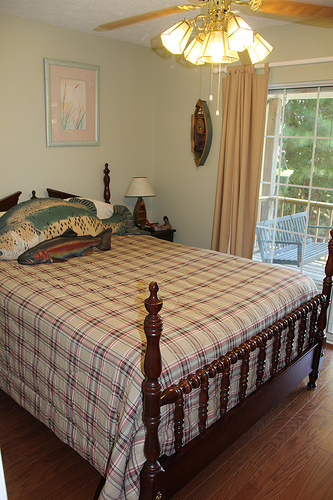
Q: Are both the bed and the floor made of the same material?
A: Yes, both the bed and the floor are made of wood.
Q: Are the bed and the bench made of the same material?
A: Yes, both the bed and the bench are made of wood.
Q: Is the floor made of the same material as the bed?
A: Yes, both the floor and the bed are made of wood.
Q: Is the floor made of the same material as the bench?
A: Yes, both the floor and the bench are made of wood.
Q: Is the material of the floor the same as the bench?
A: Yes, both the floor and the bench are made of wood.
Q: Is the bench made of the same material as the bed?
A: Yes, both the bench and the bed are made of wood.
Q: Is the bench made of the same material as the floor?
A: Yes, both the bench and the floor are made of wood.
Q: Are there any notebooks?
A: No, there are no notebooks.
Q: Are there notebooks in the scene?
A: No, there are no notebooks.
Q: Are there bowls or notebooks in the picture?
A: No, there are no notebooks or bowls.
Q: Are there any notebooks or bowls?
A: No, there are no notebooks or bowls.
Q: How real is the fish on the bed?
A: The fish is fake.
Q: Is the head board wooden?
A: Yes, the head board is wooden.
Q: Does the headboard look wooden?
A: Yes, the headboard is wooden.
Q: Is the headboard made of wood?
A: Yes, the headboard is made of wood.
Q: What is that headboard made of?
A: The headboard is made of wood.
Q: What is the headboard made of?
A: The headboard is made of wood.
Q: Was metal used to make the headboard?
A: No, the headboard is made of wood.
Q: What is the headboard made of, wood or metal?
A: The headboard is made of wood.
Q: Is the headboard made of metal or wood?
A: The headboard is made of wood.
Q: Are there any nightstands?
A: Yes, there is a nightstand.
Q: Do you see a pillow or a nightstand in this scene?
A: Yes, there is a nightstand.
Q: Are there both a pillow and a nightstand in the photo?
A: Yes, there are both a nightstand and a pillow.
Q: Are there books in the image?
A: No, there are no books.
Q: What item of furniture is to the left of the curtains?
A: The piece of furniture is a nightstand.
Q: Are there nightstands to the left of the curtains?
A: Yes, there is a nightstand to the left of the curtains.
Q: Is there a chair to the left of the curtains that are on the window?
A: No, there is a nightstand to the left of the curtains.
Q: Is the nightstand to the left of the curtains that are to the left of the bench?
A: Yes, the nightstand is to the left of the curtains.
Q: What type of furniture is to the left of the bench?
A: The piece of furniture is a nightstand.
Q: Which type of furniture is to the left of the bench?
A: The piece of furniture is a nightstand.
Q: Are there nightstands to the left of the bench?
A: Yes, there is a nightstand to the left of the bench.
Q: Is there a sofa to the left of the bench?
A: No, there is a nightstand to the left of the bench.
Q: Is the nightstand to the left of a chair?
A: No, the nightstand is to the left of the bench.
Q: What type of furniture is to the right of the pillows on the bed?
A: The piece of furniture is a nightstand.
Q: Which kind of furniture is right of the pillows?
A: The piece of furniture is a nightstand.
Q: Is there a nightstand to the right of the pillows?
A: Yes, there is a nightstand to the right of the pillows.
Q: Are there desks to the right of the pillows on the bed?
A: No, there is a nightstand to the right of the pillows.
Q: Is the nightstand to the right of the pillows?
A: Yes, the nightstand is to the right of the pillows.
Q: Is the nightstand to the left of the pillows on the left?
A: No, the nightstand is to the right of the pillows.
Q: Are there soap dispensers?
A: No, there are no soap dispensers.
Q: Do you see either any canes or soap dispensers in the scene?
A: No, there are no soap dispensers or canes.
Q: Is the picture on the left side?
A: Yes, the picture is on the left of the image.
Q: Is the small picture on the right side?
A: No, the picture is on the left of the image.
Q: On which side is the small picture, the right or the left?
A: The picture is on the left of the image.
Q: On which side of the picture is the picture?
A: The picture is on the left of the image.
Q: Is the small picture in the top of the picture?
A: Yes, the picture is in the top of the image.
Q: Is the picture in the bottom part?
A: No, the picture is in the top of the image.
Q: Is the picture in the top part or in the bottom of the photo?
A: The picture is in the top of the image.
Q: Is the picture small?
A: Yes, the picture is small.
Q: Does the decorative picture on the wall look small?
A: Yes, the picture is small.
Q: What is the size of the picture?
A: The picture is small.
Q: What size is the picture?
A: The picture is small.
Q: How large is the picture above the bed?
A: The picture is small.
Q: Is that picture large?
A: No, the picture is small.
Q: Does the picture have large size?
A: No, the picture is small.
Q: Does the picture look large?
A: No, the picture is small.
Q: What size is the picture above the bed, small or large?
A: The picture is small.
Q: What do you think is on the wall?
A: The picture is on the wall.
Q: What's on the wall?
A: The picture is on the wall.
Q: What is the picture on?
A: The picture is on the wall.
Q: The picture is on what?
A: The picture is on the wall.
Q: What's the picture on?
A: The picture is on the wall.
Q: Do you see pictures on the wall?
A: Yes, there is a picture on the wall.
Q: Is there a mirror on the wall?
A: No, there is a picture on the wall.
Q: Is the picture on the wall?
A: Yes, the picture is on the wall.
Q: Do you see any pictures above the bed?
A: Yes, there is a picture above the bed.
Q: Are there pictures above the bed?
A: Yes, there is a picture above the bed.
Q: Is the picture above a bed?
A: Yes, the picture is above a bed.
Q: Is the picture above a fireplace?
A: No, the picture is above a bed.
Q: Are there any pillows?
A: Yes, there are pillows.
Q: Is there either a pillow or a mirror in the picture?
A: Yes, there are pillows.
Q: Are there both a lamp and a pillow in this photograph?
A: Yes, there are both a pillow and a lamp.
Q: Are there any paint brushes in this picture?
A: No, there are no paint brushes.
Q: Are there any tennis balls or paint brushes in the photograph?
A: No, there are no paint brushes or tennis balls.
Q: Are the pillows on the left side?
A: Yes, the pillows are on the left of the image.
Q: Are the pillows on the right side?
A: No, the pillows are on the left of the image.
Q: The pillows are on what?
A: The pillows are on the bed.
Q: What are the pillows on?
A: The pillows are on the bed.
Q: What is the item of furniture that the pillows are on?
A: The piece of furniture is a bed.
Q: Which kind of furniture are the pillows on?
A: The pillows are on the bed.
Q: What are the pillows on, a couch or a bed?
A: The pillows are on a bed.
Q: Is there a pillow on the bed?
A: Yes, there are pillows on the bed.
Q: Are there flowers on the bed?
A: No, there are pillows on the bed.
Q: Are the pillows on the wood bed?
A: Yes, the pillows are on the bed.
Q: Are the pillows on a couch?
A: No, the pillows are on the bed.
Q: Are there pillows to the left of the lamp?
A: Yes, there are pillows to the left of the lamp.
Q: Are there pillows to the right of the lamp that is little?
A: No, the pillows are to the left of the lamp.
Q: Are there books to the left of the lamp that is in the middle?
A: No, there are pillows to the left of the lamp.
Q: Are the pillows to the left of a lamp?
A: Yes, the pillows are to the left of a lamp.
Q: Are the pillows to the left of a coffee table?
A: No, the pillows are to the left of a lamp.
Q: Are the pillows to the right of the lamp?
A: No, the pillows are to the left of the lamp.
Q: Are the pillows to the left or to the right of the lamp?
A: The pillows are to the left of the lamp.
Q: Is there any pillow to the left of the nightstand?
A: Yes, there are pillows to the left of the nightstand.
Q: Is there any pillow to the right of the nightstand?
A: No, the pillows are to the left of the nightstand.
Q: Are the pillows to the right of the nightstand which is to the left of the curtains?
A: No, the pillows are to the left of the nightstand.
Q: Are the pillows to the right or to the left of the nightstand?
A: The pillows are to the left of the nightstand.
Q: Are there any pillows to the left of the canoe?
A: Yes, there are pillows to the left of the canoe.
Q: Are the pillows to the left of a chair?
A: No, the pillows are to the left of the kayak.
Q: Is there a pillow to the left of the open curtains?
A: Yes, there are pillows to the left of the curtains.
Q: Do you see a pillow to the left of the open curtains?
A: Yes, there are pillows to the left of the curtains.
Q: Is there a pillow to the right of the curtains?
A: No, the pillows are to the left of the curtains.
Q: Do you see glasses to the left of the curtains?
A: No, there are pillows to the left of the curtains.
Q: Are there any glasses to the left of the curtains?
A: No, there are pillows to the left of the curtains.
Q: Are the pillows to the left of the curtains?
A: Yes, the pillows are to the left of the curtains.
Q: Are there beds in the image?
A: Yes, there is a bed.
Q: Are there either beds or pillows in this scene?
A: Yes, there is a bed.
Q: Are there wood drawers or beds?
A: Yes, there is a wood bed.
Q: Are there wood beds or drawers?
A: Yes, there is a wood bed.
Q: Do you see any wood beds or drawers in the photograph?
A: Yes, there is a wood bed.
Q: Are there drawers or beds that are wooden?
A: Yes, the bed is wooden.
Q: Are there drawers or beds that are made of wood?
A: Yes, the bed is made of wood.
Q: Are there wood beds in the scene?
A: Yes, there is a wood bed.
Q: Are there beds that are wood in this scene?
A: Yes, there is a wood bed.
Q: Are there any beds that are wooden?
A: Yes, there is a bed that is wooden.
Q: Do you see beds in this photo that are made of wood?
A: Yes, there is a bed that is made of wood.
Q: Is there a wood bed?
A: Yes, there is a bed that is made of wood.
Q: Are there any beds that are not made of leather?
A: Yes, there is a bed that is made of wood.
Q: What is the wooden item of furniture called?
A: The piece of furniture is a bed.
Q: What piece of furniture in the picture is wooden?
A: The piece of furniture is a bed.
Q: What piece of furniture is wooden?
A: The piece of furniture is a bed.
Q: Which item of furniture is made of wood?
A: The piece of furniture is a bed.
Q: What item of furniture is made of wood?
A: The piece of furniture is a bed.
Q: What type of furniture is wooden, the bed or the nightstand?
A: The bed is wooden.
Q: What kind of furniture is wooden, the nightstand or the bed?
A: The bed is wooden.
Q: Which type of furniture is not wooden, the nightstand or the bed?
A: The nightstand is not wooden.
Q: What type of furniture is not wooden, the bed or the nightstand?
A: The nightstand is not wooden.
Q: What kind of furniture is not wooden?
A: The furniture is a nightstand.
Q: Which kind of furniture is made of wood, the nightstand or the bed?
A: The bed is made of wood.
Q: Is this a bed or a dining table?
A: This is a bed.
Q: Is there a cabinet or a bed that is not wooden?
A: No, there is a bed but it is wooden.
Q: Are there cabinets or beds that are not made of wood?
A: No, there is a bed but it is made of wood.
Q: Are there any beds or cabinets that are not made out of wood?
A: No, there is a bed but it is made of wood.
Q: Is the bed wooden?
A: Yes, the bed is wooden.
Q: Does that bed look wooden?
A: Yes, the bed is wooden.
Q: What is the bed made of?
A: The bed is made of wood.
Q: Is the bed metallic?
A: No, the bed is wooden.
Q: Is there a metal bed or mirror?
A: No, there is a bed but it is wooden.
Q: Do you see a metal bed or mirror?
A: No, there is a bed but it is wooden.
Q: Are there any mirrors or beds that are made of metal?
A: No, there is a bed but it is made of wood.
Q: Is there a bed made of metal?
A: No, there is a bed but it is made of wood.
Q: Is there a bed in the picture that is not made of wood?
A: No, there is a bed but it is made of wood.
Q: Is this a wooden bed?
A: Yes, this is a wooden bed.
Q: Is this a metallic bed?
A: No, this is a wooden bed.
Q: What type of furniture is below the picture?
A: The piece of furniture is a bed.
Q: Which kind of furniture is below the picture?
A: The piece of furniture is a bed.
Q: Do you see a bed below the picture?
A: Yes, there is a bed below the picture.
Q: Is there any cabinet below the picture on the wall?
A: No, there is a bed below the picture.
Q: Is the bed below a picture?
A: Yes, the bed is below a picture.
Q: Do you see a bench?
A: Yes, there is a bench.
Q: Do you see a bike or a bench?
A: Yes, there is a bench.